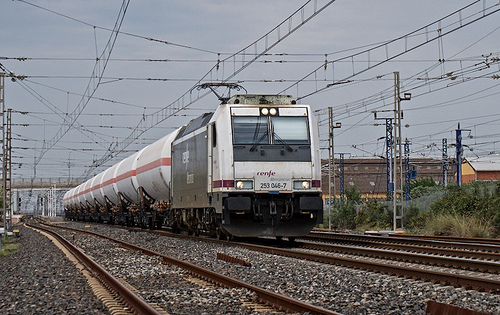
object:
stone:
[308, 278, 314, 281]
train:
[62, 94, 327, 242]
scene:
[0, 0, 500, 315]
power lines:
[0, 74, 500, 81]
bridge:
[0, 176, 93, 192]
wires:
[220, 86, 229, 99]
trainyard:
[0, 213, 500, 315]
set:
[22, 195, 345, 315]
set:
[225, 239, 500, 292]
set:
[296, 216, 500, 250]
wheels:
[214, 220, 223, 240]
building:
[319, 156, 462, 203]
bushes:
[427, 180, 500, 238]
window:
[231, 116, 311, 146]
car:
[134, 125, 187, 234]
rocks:
[304, 268, 314, 273]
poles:
[9, 109, 12, 229]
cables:
[0, 57, 500, 64]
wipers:
[271, 123, 295, 153]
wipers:
[248, 122, 270, 152]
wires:
[11, 0, 500, 57]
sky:
[0, 0, 500, 212]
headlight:
[293, 180, 311, 190]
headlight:
[234, 179, 254, 189]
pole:
[390, 73, 397, 231]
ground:
[0, 198, 500, 315]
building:
[453, 152, 499, 185]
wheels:
[170, 221, 180, 234]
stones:
[287, 288, 295, 293]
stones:
[353, 300, 362, 306]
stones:
[317, 286, 322, 290]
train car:
[170, 93, 324, 242]